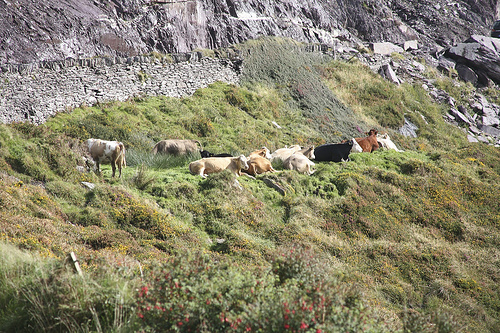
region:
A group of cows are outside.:
[57, 111, 394, 171]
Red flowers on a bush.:
[105, 265, 350, 330]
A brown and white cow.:
[85, 126, 130, 176]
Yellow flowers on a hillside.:
[31, 192, 172, 248]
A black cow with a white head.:
[315, 131, 365, 166]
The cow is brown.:
[356, 123, 381, 149]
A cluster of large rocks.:
[432, 28, 497, 89]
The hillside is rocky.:
[12, 13, 212, 78]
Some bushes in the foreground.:
[0, 241, 385, 329]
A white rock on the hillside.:
[368, 30, 410, 55]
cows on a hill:
[84, 122, 415, 192]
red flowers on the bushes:
[114, 211, 339, 331]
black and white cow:
[305, 112, 410, 191]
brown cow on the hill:
[348, 120, 402, 154]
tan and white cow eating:
[49, 125, 156, 191]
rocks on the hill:
[364, 20, 492, 136]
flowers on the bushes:
[328, 168, 494, 290]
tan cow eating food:
[140, 124, 198, 164]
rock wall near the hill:
[24, 42, 249, 104]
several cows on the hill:
[34, 98, 499, 208]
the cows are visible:
[161, 67, 422, 222]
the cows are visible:
[179, 136, 388, 318]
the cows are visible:
[234, 170, 384, 293]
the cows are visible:
[199, 143, 334, 251]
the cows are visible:
[199, 76, 464, 314]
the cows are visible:
[191, 94, 333, 222]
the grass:
[330, 206, 462, 324]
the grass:
[280, 234, 353, 314]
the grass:
[277, 239, 321, 274]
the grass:
[274, 122, 388, 322]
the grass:
[291, 194, 377, 299]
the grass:
[301, 250, 365, 325]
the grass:
[299, 144, 416, 287]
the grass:
[146, 151, 433, 331]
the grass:
[357, 197, 422, 308]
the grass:
[364, 267, 402, 321]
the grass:
[333, 220, 391, 311]